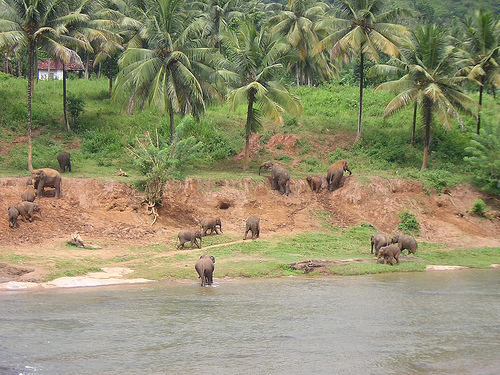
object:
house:
[35, 59, 92, 81]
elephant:
[243, 215, 261, 240]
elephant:
[306, 176, 323, 194]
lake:
[0, 265, 500, 375]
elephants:
[57, 152, 72, 173]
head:
[216, 217, 223, 234]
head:
[258, 160, 273, 176]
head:
[343, 159, 352, 176]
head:
[193, 230, 202, 249]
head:
[33, 204, 44, 221]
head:
[370, 234, 375, 254]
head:
[392, 234, 399, 245]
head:
[31, 169, 47, 186]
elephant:
[200, 216, 223, 236]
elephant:
[258, 160, 292, 196]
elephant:
[326, 159, 353, 194]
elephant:
[29, 168, 63, 200]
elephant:
[17, 201, 44, 223]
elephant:
[21, 185, 38, 203]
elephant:
[8, 205, 19, 229]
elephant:
[194, 254, 215, 287]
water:
[0, 267, 499, 375]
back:
[195, 265, 212, 286]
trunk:
[370, 242, 373, 255]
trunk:
[220, 225, 224, 234]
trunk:
[199, 238, 202, 249]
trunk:
[259, 163, 265, 175]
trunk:
[346, 169, 351, 175]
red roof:
[37, 59, 92, 70]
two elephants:
[306, 159, 352, 195]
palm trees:
[108, 0, 303, 171]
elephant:
[391, 233, 419, 255]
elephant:
[375, 244, 401, 266]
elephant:
[370, 233, 391, 257]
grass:
[258, 206, 500, 278]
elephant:
[175, 230, 203, 251]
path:
[17, 237, 278, 276]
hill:
[0, 73, 500, 281]